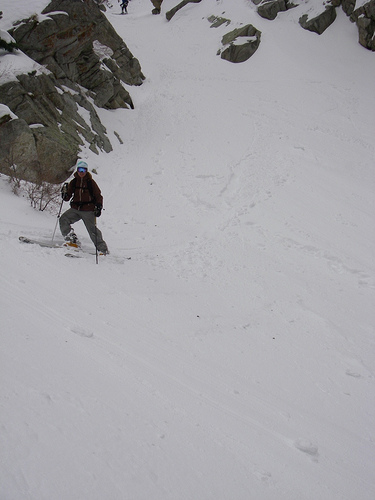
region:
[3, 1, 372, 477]
A winter scene.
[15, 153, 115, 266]
A skier in the snow.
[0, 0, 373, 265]
The skiers are traveling down hill.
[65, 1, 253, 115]
A skier between rocks.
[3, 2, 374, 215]
Rocks along the ski trail.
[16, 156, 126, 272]
A person is skiing.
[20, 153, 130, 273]
The skier is wearing grey pants.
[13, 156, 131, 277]
The skier is in motion.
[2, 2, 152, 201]
Large rocks along the ski slope.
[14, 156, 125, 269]
The person is holding ski poles.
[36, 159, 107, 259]
Skier pauses in thick snow at flat area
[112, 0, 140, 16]
Skier making their way down the mountain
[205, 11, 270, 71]
Rock partially covered in snow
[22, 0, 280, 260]
Two skiers on a snowy mountain slope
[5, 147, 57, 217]
Plant shrubs covered in snow on mountain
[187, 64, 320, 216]
Mountain blanketed in snow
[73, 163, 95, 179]
Face of skier with prominent eye protection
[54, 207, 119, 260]
Skier wearing thick grey pants and yellow shoes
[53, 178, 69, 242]
Skier holding ski pole in downright motion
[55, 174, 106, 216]
man wearing black jacket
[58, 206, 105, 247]
man wearing gray ski pants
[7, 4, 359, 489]
white snow covering mountainside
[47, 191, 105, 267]
man holding black ski poles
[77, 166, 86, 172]
man wearing blue goggles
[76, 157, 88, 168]
man wearing white hat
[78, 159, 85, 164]
rocks lining snowy slope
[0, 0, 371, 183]
grey rocks lining ski slope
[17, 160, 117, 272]
man standing with white skis on ski slope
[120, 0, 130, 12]
Person way up on a snow slope.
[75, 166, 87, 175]
Blue goggles on a man's face.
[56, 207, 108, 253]
Grey pants on a man.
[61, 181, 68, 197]
A right hand black glove.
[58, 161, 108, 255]
A man in blue goggles and grey pants.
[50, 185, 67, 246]
A grey ski pole.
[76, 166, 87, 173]
Blue tinted goggles.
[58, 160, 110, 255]
person on the ski slope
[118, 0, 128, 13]
person skiing down a hill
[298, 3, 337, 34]
large rock with snow on it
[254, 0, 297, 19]
large rock with snow on it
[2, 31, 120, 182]
large rock with snow on it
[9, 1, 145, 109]
large rock with snow on it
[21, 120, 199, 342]
a man is skiing on the snow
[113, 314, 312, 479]
an area of snow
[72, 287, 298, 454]
an area of white snow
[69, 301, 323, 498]
a ground covered in snow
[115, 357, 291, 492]
snow covering the ground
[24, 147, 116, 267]
a man on skis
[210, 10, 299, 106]
snow on a mountain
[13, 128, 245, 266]
a man sking on a mountain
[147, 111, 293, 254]
snow covering the ground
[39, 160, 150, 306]
a man is skiing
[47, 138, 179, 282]
a man standing on skis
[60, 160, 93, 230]
a man holding ski poles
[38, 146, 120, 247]
a man wearing goggles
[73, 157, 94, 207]
a man wearing a hat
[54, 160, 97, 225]
a man wearing a jacket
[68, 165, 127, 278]
a man wearing pants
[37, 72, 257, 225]
snow with ski tracks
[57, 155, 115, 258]
person on a slope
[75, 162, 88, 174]
ski goggles on a person's face